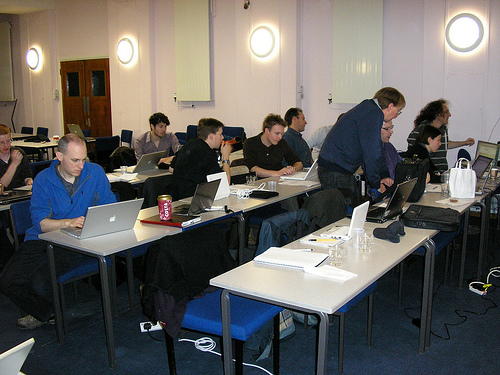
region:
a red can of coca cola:
[157, 198, 170, 218]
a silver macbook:
[66, 197, 148, 241]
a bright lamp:
[245, 26, 280, 63]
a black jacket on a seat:
[147, 226, 234, 315]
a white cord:
[174, 328, 272, 373]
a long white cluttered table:
[218, 207, 434, 335]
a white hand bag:
[444, 153, 482, 198]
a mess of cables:
[403, 256, 498, 338]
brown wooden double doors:
[57, 54, 113, 138]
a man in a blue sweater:
[32, 129, 117, 236]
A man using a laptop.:
[1, 132, 146, 327]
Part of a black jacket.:
[171, 261, 193, 286]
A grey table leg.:
[98, 254, 119, 368]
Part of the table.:
[262, 271, 278, 286]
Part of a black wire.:
[452, 304, 479, 326]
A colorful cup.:
[156, 194, 171, 222]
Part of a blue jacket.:
[333, 140, 348, 156]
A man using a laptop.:
[240, 115, 315, 180]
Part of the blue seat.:
[201, 307, 221, 327]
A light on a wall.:
[115, 34, 138, 69]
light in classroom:
[249, 20, 278, 60]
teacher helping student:
[319, 81, 404, 187]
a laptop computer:
[66, 197, 146, 239]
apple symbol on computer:
[107, 212, 117, 224]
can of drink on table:
[157, 194, 174, 219]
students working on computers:
[1, 5, 496, 374]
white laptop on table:
[325, 202, 371, 239]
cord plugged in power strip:
[140, 320, 167, 340]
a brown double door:
[59, 55, 113, 135]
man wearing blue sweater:
[33, 168, 112, 220]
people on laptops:
[4, 95, 328, 256]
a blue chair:
[141, 238, 292, 373]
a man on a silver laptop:
[33, 143, 157, 256]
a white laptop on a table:
[306, 190, 379, 254]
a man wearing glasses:
[366, 78, 404, 120]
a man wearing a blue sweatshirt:
[17, 133, 130, 237]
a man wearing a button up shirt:
[115, 103, 191, 155]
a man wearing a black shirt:
[249, 113, 296, 189]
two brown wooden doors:
[45, 52, 135, 154]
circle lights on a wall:
[5, 8, 499, 83]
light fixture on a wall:
[19, 43, 54, 81]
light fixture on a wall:
[112, 30, 137, 75]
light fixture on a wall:
[243, 14, 282, 76]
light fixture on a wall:
[441, 2, 488, 62]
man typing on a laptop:
[27, 131, 143, 246]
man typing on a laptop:
[243, 114, 318, 190]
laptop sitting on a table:
[172, 173, 225, 219]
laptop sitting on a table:
[364, 176, 421, 224]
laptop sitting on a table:
[322, 200, 371, 243]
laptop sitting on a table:
[116, 148, 170, 174]